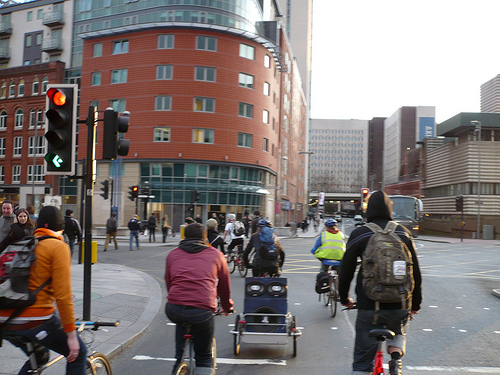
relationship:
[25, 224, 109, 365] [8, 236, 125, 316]
man wearing jacket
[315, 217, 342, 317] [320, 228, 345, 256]
person in vest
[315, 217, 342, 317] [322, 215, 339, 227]
person in helment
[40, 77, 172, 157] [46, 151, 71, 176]
stop light with arrow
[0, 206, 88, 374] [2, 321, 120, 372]
man riding bike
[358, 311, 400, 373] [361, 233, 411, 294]
bicycle with backpack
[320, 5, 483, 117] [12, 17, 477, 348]
clear sky over city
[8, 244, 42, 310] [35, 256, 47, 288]
backpack on back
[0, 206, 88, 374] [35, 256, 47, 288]
man has back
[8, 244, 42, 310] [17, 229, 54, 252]
backpack has straps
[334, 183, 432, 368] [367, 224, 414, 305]
man has backpack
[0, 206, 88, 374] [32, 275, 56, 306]
man has straps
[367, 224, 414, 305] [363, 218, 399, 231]
backpack has straps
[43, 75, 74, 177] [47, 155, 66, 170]
traffic signal has arrow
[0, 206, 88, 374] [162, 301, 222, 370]
man wearing blue jeans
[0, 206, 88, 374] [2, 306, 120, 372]
man riding bike